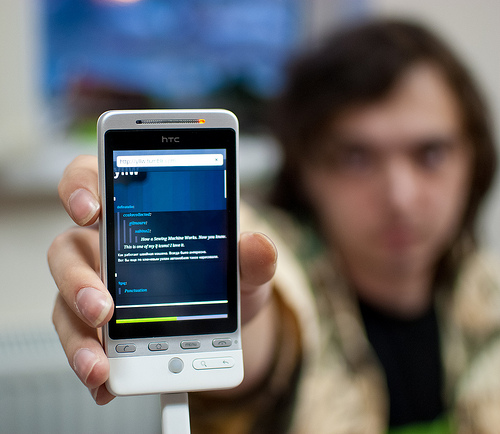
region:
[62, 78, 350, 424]
a phone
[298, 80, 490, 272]
a blurred man's face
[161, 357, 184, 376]
a foggy translucent power button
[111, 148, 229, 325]
the blue screen of a cell phone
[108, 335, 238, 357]
a row of gray buttons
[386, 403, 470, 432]
a green stripe on a man's shirt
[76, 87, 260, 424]
a white and gray HTC cell phone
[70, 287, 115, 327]
a man's middle finger nail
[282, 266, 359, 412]
a pattern shirt on a man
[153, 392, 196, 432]
a white charging plug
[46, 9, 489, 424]
a man holding up a cell phone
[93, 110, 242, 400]
White cellphone in foreground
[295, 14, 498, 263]
caucasian male holding phone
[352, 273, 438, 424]
black undershirt of man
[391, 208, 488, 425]
Light colored coat on man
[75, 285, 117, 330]
Finger nail on man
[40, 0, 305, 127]
Large blue screen in background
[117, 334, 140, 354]
call button on cellphone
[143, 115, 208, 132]
Speaker for ear on cellphone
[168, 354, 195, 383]
microphone for mouth on cellphone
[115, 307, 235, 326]
green download progress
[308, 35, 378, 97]
The mans hair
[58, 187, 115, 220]
Nails of man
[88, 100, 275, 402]
man holding smartphone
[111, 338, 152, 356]
buttons on smartphone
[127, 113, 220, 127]
Speaker of smartphone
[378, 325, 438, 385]
Man is wearing a black shirt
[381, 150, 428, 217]
Nose of the man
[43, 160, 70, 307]
Fingers of the man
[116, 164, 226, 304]
Screen of the smartphone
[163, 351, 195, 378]
Home button on smartphone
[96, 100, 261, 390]
cell phone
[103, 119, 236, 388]
white and gray cell phone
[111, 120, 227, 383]
white and gray HTC cell phone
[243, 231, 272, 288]
finer of person holding cell phone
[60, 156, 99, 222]
finer of person holding cell phone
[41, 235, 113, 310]
finer of person holding cell phone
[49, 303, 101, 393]
finer of person holding cell phone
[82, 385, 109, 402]
finer of person holding cell phone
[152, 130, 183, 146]
silver logo on phone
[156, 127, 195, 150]
silver HTC logo on phone